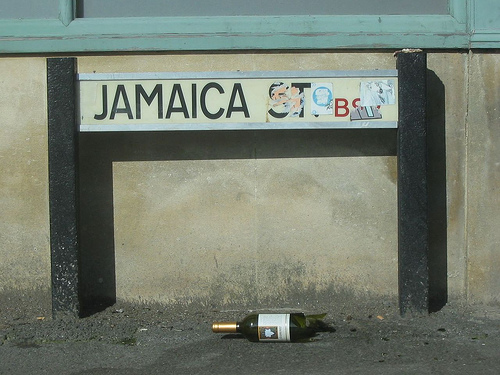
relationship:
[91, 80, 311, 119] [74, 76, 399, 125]
jamaica st painted on sign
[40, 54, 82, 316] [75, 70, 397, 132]
post holding up sign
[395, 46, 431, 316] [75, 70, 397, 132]
post holding up sign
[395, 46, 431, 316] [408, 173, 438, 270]
post holding up sign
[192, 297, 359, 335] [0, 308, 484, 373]
bottle lying on ground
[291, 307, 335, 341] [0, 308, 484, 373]
glass shard lying on ground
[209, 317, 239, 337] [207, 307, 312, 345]
cap topping bottle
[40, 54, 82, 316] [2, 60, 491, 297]
post standing in front of wall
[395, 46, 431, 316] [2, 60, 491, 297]
post standing in front of wall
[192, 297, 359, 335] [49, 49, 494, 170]
bottle under board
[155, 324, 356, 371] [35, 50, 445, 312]
shadow of street board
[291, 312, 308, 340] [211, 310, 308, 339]
bottom of bottle